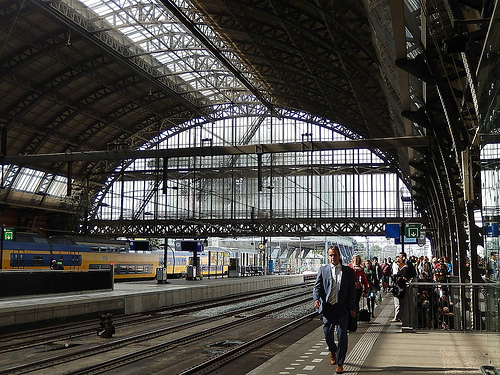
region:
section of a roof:
[283, 68, 315, 102]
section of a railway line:
[171, 332, 188, 337]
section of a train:
[93, 254, 118, 266]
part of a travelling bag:
[361, 312, 365, 316]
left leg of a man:
[340, 326, 347, 351]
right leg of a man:
[324, 327, 328, 349]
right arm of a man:
[314, 280, 319, 297]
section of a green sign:
[410, 230, 417, 236]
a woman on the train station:
[368, 270, 373, 294]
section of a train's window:
[131, 267, 142, 273]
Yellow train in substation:
[11, 226, 235, 286]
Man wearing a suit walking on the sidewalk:
[308, 240, 368, 370]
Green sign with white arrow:
[406, 220, 424, 245]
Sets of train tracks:
[133, 310, 272, 362]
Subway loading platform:
[371, 249, 470, 369]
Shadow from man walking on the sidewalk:
[360, 355, 484, 373]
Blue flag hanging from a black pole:
[382, 217, 407, 254]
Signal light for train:
[254, 242, 271, 269]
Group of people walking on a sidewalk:
[356, 246, 396, 313]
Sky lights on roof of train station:
[33, 7, 310, 129]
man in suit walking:
[306, 242, 358, 367]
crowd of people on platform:
[357, 254, 417, 317]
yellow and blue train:
[51, 232, 200, 279]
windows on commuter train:
[90, 241, 146, 260]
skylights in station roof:
[112, 9, 257, 123]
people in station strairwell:
[407, 263, 447, 323]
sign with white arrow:
[403, 220, 424, 245]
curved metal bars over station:
[424, 85, 484, 315]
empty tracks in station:
[139, 312, 264, 354]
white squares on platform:
[291, 345, 327, 373]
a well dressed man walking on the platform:
[313, 243, 358, 373]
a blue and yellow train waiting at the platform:
[9, 230, 238, 281]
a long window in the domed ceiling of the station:
[76, 4, 264, 110]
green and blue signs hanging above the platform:
[386, 219, 423, 247]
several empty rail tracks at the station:
[168, 299, 273, 364]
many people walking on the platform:
[357, 255, 437, 285]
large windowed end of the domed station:
[77, 113, 429, 298]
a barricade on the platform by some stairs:
[410, 284, 498, 336]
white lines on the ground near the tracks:
[283, 346, 327, 374]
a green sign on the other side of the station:
[4, 228, 15, 245]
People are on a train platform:
[13, 9, 467, 364]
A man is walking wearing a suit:
[271, 215, 413, 364]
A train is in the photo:
[4, 199, 340, 308]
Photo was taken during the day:
[43, 138, 480, 368]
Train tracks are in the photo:
[26, 247, 395, 372]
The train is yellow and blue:
[8, 207, 336, 307]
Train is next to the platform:
[9, 180, 325, 325]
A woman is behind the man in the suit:
[277, 208, 444, 365]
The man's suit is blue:
[249, 228, 399, 369]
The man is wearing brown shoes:
[282, 212, 383, 372]